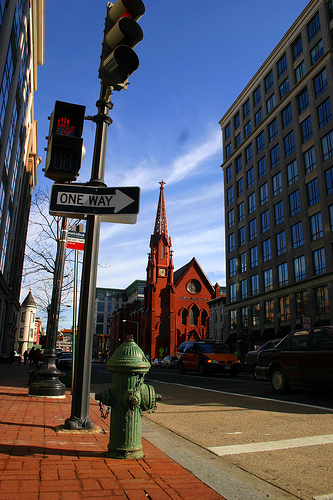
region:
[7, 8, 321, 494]
A city street scene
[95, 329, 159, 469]
A green fire hydrant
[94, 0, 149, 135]
This is a traffic light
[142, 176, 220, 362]
This building is a church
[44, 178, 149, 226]
A One Way sign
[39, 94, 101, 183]
This is a crosswalk light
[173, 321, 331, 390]
Traffic is on the street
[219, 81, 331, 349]
A building is along the street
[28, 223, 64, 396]
A lamp post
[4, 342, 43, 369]
People are walking on the sidewalk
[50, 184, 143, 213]
black and white one way sign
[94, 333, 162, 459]
a green fire hydrant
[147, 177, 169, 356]
spire of a church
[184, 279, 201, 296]
round window in a church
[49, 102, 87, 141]
a don't walk sign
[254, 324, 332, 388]
rear end of a car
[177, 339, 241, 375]
an orange minivan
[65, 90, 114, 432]
a grey metal pole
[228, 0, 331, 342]
a tall building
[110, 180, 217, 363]
a red brick church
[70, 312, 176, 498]
a water pipe on the sidewalk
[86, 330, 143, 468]
a water pipe on the sidewalk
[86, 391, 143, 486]
a water pipe on the sidewalk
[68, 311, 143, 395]
a water pipe on the sidewalk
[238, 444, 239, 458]
the line is white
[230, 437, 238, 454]
the line is white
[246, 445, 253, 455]
the line is white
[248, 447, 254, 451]
the line is white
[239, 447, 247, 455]
the line is white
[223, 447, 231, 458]
the line is white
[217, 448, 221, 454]
the line is white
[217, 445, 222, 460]
the line is white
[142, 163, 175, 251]
A steeple on a church.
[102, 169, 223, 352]
The church building is red.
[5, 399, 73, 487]
Red bricks on the sidewalk.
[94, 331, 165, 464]
The fire hydrant is green.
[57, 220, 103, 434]
The pole on the sidewalk is black.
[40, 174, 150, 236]
A one way sign attached to the pole.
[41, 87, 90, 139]
A red hand light attached to the pole.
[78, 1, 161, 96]
Three traffic lights at the top of the pole.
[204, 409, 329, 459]
A white line painted on the street.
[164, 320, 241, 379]
The car is orange.